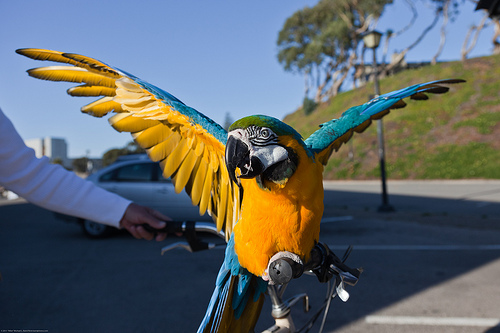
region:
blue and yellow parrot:
[8, 39, 452, 314]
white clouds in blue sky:
[155, 25, 176, 52]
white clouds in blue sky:
[192, 2, 242, 44]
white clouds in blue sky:
[198, 55, 260, 123]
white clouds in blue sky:
[172, 5, 209, 45]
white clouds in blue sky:
[144, 21, 196, 65]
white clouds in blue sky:
[97, 23, 169, 73]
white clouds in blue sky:
[72, 6, 142, 40]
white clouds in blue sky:
[177, 43, 221, 87]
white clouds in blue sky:
[208, 42, 240, 87]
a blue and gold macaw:
[18, 45, 465, 331]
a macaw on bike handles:
[16, 47, 463, 332]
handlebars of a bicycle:
[159, 219, 356, 331]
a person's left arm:
[1, 108, 168, 233]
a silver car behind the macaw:
[55, 158, 215, 240]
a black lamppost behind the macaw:
[364, 31, 396, 206]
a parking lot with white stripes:
[6, 203, 497, 326]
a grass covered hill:
[279, 54, 498, 179]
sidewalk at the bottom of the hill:
[323, 181, 498, 227]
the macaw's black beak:
[226, 139, 261, 182]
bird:
[41, 49, 483, 320]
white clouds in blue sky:
[135, 16, 193, 48]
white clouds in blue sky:
[201, 53, 236, 105]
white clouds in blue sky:
[214, 55, 248, 70]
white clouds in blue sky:
[155, 35, 200, 57]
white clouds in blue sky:
[220, 38, 264, 63]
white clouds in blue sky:
[132, 32, 179, 66]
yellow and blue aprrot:
[58, 41, 453, 319]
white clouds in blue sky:
[407, 8, 467, 38]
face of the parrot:
[188, 118, 300, 193]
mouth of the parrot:
[210, 140, 244, 187]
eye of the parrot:
[239, 96, 279, 151]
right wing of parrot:
[326, 68, 441, 169]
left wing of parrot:
[34, 14, 216, 189]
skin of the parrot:
[158, 88, 208, 163]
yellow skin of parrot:
[258, 187, 295, 257]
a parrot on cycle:
[161, 103, 391, 332]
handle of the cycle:
[244, 231, 329, 327]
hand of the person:
[26, 150, 109, 239]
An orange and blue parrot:
[15, 48, 468, 332]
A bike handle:
[134, 215, 363, 332]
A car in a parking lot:
[50, 158, 215, 239]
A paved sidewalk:
[322, 176, 499, 220]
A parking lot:
[0, 201, 499, 332]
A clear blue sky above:
[0, 1, 499, 157]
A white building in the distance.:
[20, 136, 67, 164]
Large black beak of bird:
[224, 136, 264, 188]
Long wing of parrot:
[14, 47, 238, 238]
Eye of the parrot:
[260, 129, 268, 136]